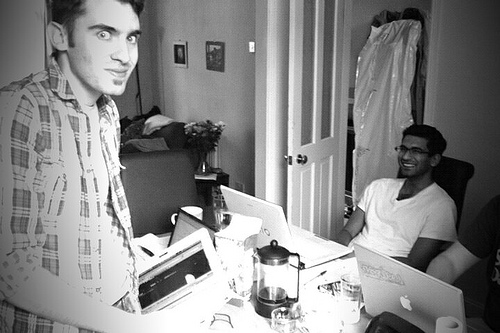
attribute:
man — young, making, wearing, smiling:
[6, 12, 183, 279]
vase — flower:
[169, 108, 274, 247]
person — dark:
[353, 104, 465, 201]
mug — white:
[336, 248, 356, 316]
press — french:
[163, 223, 224, 291]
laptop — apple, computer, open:
[352, 234, 483, 330]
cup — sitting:
[314, 248, 377, 317]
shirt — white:
[322, 167, 460, 253]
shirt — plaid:
[11, 102, 78, 224]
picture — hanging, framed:
[150, 26, 245, 100]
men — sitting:
[46, 13, 483, 287]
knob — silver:
[280, 131, 316, 170]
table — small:
[92, 184, 351, 332]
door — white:
[239, 10, 378, 215]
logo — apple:
[387, 265, 442, 316]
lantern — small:
[208, 202, 340, 328]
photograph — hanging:
[145, 25, 251, 86]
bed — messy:
[119, 52, 244, 182]